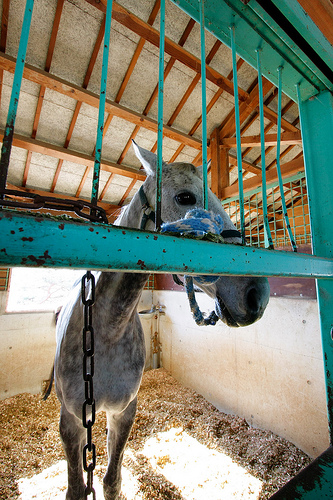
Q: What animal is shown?
A: A horse.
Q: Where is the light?
A: On the ground.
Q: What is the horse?
A: Tied up.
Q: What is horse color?
A: Grey.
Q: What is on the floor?
A: Sawdust.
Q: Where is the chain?
A: On the bars.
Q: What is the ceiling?
A: Wooden.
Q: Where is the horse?
A: Stall.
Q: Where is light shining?
A: Into stall.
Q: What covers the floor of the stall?
A: Bedding.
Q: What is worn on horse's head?
A: Halter.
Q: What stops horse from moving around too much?
A: Rope.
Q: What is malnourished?
A: Horse.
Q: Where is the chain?
A: Woven fence.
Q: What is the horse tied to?
A: Bars.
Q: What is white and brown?
A: Horse.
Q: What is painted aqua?
A: Bars.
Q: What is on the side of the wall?
A: Bars.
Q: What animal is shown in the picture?
A: A horse.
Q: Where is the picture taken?
A: A farm stall.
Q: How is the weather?
A: Sunny and clear.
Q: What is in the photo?
A: A horse.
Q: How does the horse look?
A: Thin.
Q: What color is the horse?
A: White and black.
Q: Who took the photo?
A: Max.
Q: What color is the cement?
A: Grey.